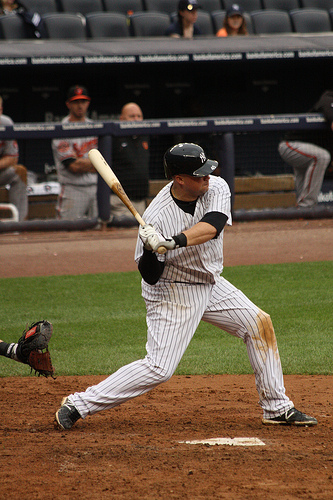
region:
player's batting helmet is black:
[161, 139, 221, 203]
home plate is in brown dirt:
[1, 377, 332, 498]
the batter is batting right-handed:
[72, 132, 215, 269]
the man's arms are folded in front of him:
[47, 85, 98, 177]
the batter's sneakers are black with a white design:
[49, 391, 324, 432]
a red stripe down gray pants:
[280, 136, 331, 214]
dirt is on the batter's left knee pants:
[244, 308, 283, 360]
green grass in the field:
[49, 273, 144, 357]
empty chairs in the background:
[46, 10, 171, 39]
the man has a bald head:
[118, 102, 146, 124]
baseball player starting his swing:
[46, 134, 323, 461]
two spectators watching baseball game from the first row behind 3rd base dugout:
[166, 1, 255, 39]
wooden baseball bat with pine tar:
[79, 142, 161, 255]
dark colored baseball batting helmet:
[161, 133, 217, 181]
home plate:
[175, 430, 269, 453]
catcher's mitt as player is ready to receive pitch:
[11, 314, 57, 373]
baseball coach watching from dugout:
[49, 81, 108, 221]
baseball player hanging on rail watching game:
[282, 83, 326, 205]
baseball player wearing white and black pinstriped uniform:
[51, 138, 323, 436]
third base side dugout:
[1, 64, 330, 218]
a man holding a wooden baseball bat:
[87, 147, 168, 257]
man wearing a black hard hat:
[162, 140, 219, 180]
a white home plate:
[179, 434, 266, 445]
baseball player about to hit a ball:
[54, 140, 318, 431]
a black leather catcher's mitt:
[16, 319, 54, 376]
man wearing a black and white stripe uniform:
[68, 175, 291, 420]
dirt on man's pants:
[245, 310, 281, 371]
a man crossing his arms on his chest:
[53, 83, 104, 218]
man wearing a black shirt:
[112, 129, 148, 199]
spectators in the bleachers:
[1, 0, 332, 35]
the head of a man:
[160, 139, 222, 197]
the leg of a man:
[74, 282, 201, 416]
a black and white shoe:
[53, 392, 83, 434]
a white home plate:
[173, 432, 269, 452]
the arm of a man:
[178, 178, 231, 249]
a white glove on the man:
[144, 227, 174, 255]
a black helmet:
[162, 140, 222, 181]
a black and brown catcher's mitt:
[12, 316, 69, 380]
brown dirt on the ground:
[0, 373, 332, 499]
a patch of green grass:
[0, 259, 332, 378]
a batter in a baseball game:
[42, 117, 326, 473]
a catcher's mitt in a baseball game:
[14, 310, 64, 383]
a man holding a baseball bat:
[81, 136, 173, 261]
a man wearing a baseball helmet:
[156, 140, 222, 179]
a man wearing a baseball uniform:
[64, 184, 297, 431]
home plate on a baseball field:
[169, 422, 273, 455]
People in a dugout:
[49, 68, 167, 205]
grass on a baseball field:
[28, 273, 330, 369]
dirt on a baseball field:
[13, 373, 328, 491]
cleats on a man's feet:
[47, 394, 326, 438]